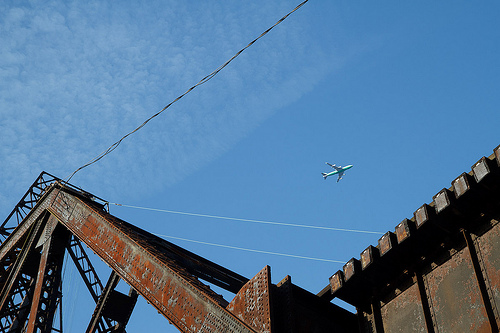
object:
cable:
[90, 55, 233, 166]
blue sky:
[1, 1, 498, 333]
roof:
[326, 140, 500, 289]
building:
[324, 145, 498, 332]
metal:
[0, 170, 351, 332]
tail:
[319, 172, 327, 181]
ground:
[348, 82, 394, 124]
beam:
[0, 170, 293, 333]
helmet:
[0, 2, 346, 202]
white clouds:
[0, 0, 320, 196]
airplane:
[320, 162, 354, 183]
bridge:
[0, 169, 499, 333]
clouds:
[17, 9, 291, 134]